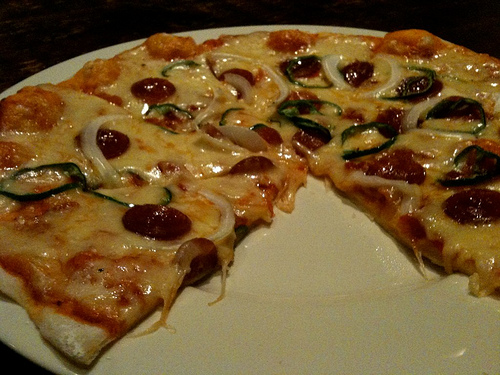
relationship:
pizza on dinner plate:
[0, 26, 500, 373] [0, 23, 499, 374]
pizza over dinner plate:
[0, 26, 500, 373] [0, 23, 499, 374]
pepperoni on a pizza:
[294, 131, 317, 153] [0, 26, 500, 373]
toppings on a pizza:
[130, 75, 192, 133] [0, 26, 500, 373]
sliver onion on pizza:
[321, 50, 376, 92] [164, 29, 498, 289]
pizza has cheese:
[0, 26, 500, 373] [1, 36, 498, 336]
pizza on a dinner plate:
[0, 26, 500, 373] [0, 23, 499, 374]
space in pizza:
[86, 170, 498, 368] [0, 26, 500, 373]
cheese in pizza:
[96, 92, 457, 237] [14, 30, 478, 336]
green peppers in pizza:
[3, 72, 483, 212] [0, 26, 500, 373]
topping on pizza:
[120, 202, 195, 240] [0, 26, 500, 373]